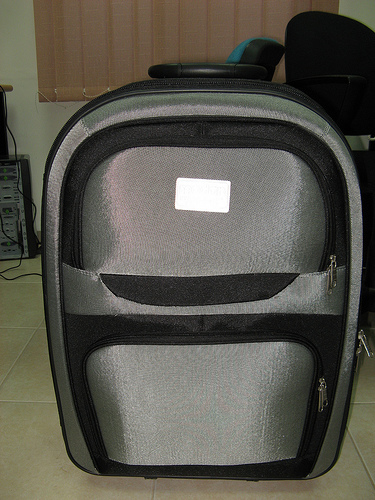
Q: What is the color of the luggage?
A: Black and silver.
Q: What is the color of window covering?
A: Tan.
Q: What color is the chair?
A: Black.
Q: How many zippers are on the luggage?
A: Three.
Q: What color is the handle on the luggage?
A: Black.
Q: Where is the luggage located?
A: On the tile floor.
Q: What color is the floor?
A: Off white.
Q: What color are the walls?
A: White.